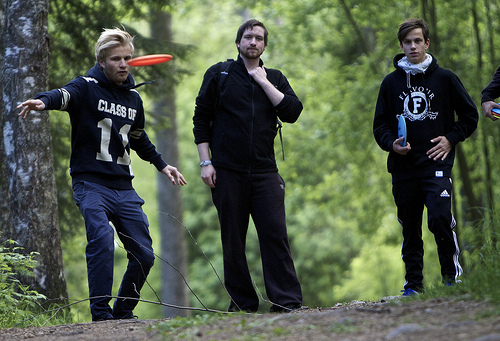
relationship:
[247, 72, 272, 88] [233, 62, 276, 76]
hand on collar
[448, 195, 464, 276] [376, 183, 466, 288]
stripe on pants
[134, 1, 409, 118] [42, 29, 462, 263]
forest behind players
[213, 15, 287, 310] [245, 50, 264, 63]
man has hair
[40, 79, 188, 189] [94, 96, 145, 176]
sweatshirt has class of 11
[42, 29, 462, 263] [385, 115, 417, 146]
men playing frisbee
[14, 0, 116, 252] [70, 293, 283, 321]
tree has branch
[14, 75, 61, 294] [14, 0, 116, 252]
trunk of tree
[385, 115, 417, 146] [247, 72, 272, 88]
frisbee in hand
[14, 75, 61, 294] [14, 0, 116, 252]
trunk on tree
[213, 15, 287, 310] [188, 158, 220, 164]
man wearing watch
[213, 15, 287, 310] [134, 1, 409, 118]
man in forest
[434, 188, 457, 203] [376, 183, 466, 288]
adidas on pants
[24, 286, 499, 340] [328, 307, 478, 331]
ground has dirt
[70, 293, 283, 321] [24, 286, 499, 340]
branch on ground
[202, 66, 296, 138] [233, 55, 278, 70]
jacket has neckline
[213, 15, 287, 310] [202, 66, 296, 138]
man wearing jacket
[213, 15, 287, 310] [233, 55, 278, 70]
man pulling neckline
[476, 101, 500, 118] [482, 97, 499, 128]
hand holding frisbees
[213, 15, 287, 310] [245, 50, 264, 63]
man with hair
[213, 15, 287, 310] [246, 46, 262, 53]
man has mouth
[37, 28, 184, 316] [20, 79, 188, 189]
men wearing sweatshirt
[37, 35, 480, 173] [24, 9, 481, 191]
men in woods